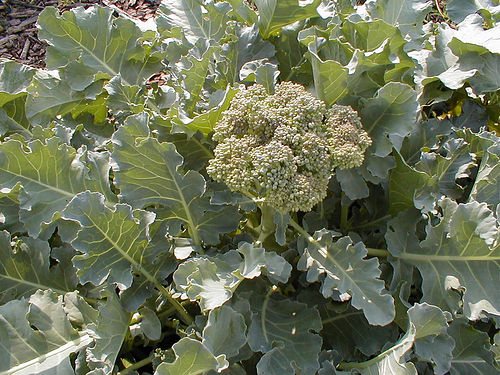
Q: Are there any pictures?
A: No, there are no pictures.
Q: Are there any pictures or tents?
A: No, there are no pictures or tents.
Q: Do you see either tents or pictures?
A: No, there are no pictures or tents.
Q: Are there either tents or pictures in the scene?
A: No, there are no pictures or tents.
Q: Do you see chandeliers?
A: No, there are no chandeliers.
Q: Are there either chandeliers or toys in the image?
A: No, there are no chandeliers or toys.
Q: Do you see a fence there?
A: No, there are no fences.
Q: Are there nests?
A: No, there are no nests.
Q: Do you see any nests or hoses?
A: No, there are no nests or hoses.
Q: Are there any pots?
A: No, there are no pots.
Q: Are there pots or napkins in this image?
A: No, there are no pots or napkins.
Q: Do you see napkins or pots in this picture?
A: No, there are no pots or napkins.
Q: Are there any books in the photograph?
A: No, there are no books.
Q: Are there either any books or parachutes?
A: No, there are no books or parachutes.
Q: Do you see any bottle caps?
A: No, there are no bottle caps.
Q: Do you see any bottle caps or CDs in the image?
A: No, there are no bottle caps or cds.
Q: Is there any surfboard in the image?
A: No, there are no surfboards.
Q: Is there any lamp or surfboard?
A: No, there are no surfboards or lamps.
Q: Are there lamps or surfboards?
A: No, there are no surfboards or lamps.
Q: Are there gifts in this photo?
A: No, there are no gifts.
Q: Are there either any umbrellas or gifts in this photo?
A: No, there are no gifts or umbrellas.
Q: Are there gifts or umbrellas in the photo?
A: No, there are no gifts or umbrellas.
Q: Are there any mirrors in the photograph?
A: No, there are no mirrors.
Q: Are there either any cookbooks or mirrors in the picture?
A: No, there are no mirrors or cookbooks.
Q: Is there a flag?
A: No, there are no flags.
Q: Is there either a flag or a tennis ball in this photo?
A: No, there are no flags or tennis balls.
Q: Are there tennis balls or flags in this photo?
A: No, there are no flags or tennis balls.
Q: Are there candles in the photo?
A: No, there are no candles.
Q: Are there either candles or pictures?
A: No, there are no candles or pictures.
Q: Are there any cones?
A: No, there are no cones.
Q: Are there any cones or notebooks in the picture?
A: No, there are no cones or notebooks.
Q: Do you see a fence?
A: No, there are no fences.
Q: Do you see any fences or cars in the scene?
A: No, there are no fences or cars.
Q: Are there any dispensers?
A: No, there are no dispensers.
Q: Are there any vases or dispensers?
A: No, there are no dispensers or vases.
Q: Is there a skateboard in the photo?
A: No, there are no skateboards.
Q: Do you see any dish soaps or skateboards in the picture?
A: No, there are no skateboards or dish soaps.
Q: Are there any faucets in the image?
A: No, there are no faucets.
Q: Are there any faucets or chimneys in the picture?
A: No, there are no faucets or chimneys.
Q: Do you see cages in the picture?
A: No, there are no cages.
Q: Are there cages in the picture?
A: No, there are no cages.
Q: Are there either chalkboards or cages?
A: No, there are no cages or chalkboards.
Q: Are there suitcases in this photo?
A: No, there are no suitcases.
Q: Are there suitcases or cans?
A: No, there are no suitcases or cans.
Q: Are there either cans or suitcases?
A: No, there are no suitcases or cans.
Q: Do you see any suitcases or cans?
A: No, there are no suitcases or cans.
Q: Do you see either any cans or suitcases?
A: No, there are no suitcases or cans.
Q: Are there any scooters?
A: No, there are no scooters.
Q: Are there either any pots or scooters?
A: No, there are no scooters or pots.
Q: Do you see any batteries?
A: No, there are no batteries.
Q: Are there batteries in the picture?
A: No, there are no batteries.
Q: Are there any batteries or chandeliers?
A: No, there are no batteries or chandeliers.